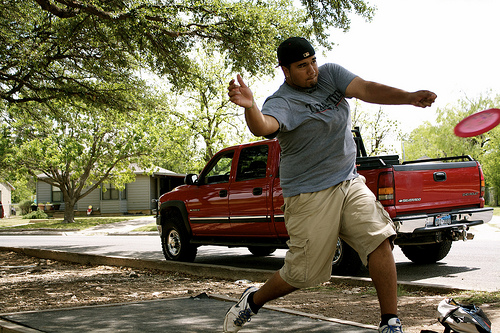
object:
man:
[223, 37, 436, 332]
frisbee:
[454, 108, 500, 138]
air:
[0, 2, 500, 331]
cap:
[275, 37, 317, 66]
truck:
[155, 133, 491, 263]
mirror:
[185, 174, 198, 185]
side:
[152, 138, 287, 261]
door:
[228, 145, 274, 237]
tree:
[0, 71, 201, 226]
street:
[0, 200, 500, 289]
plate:
[433, 215, 452, 225]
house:
[34, 161, 183, 218]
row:
[30, 202, 61, 211]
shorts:
[278, 173, 396, 288]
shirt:
[261, 64, 359, 198]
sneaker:
[223, 287, 262, 331]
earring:
[287, 76, 289, 78]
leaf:
[195, 47, 201, 52]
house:
[482, 182, 500, 207]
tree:
[462, 96, 498, 207]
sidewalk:
[1, 291, 380, 332]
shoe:
[377, 319, 402, 332]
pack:
[435, 292, 499, 332]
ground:
[2, 206, 499, 332]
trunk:
[63, 191, 80, 224]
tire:
[160, 221, 191, 261]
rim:
[168, 230, 181, 255]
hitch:
[460, 224, 469, 241]